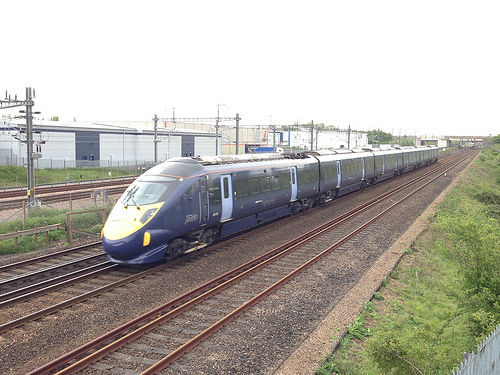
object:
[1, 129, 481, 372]
gravel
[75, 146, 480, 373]
train track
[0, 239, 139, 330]
train track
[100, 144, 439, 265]
train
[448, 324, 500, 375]
fence